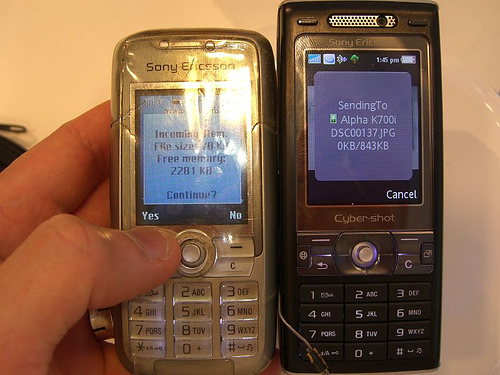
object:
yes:
[142, 211, 160, 220]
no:
[230, 211, 243, 220]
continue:
[167, 191, 210, 200]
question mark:
[211, 190, 216, 200]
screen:
[134, 88, 248, 225]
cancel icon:
[386, 190, 417, 200]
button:
[352, 241, 378, 268]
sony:
[146, 63, 178, 74]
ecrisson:
[182, 61, 235, 70]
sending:
[339, 101, 377, 112]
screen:
[305, 50, 423, 204]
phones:
[110, 0, 444, 375]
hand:
[1, 100, 278, 375]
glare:
[184, 42, 250, 166]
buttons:
[127, 237, 259, 358]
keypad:
[299, 283, 433, 363]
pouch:
[0, 122, 27, 171]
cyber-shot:
[334, 213, 396, 224]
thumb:
[0, 213, 179, 375]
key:
[224, 338, 258, 355]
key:
[131, 339, 166, 357]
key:
[173, 341, 213, 359]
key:
[131, 320, 167, 339]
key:
[174, 318, 213, 339]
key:
[129, 300, 163, 320]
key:
[220, 301, 257, 321]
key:
[174, 305, 213, 320]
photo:
[0, 0, 500, 374]